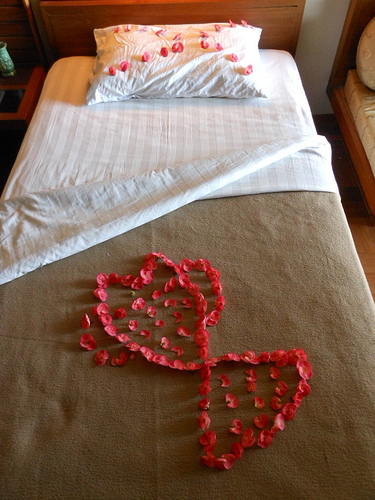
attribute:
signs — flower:
[57, 245, 326, 467]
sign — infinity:
[62, 242, 333, 479]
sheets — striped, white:
[32, 55, 317, 187]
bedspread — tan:
[16, 182, 362, 489]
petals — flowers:
[78, 245, 331, 480]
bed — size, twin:
[8, 41, 362, 481]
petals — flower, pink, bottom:
[71, 257, 332, 471]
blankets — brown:
[2, 190, 362, 481]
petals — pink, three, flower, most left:
[70, 305, 132, 373]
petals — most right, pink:
[288, 349, 320, 381]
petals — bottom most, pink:
[196, 448, 236, 473]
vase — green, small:
[1, 38, 25, 85]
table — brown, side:
[2, 54, 44, 141]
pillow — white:
[83, 14, 284, 116]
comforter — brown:
[0, 190, 372, 498]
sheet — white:
[0, 135, 338, 286]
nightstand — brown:
[0, 61, 46, 137]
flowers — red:
[76, 250, 312, 471]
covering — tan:
[1, 193, 373, 499]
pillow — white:
[84, 23, 270, 108]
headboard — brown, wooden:
[34, 0, 305, 56]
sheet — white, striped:
[0, 47, 317, 198]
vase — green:
[0, 41, 17, 79]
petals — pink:
[76, 245, 314, 469]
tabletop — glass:
[0, 60, 37, 113]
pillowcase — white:
[88, 22, 268, 107]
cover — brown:
[0, 190, 372, 498]